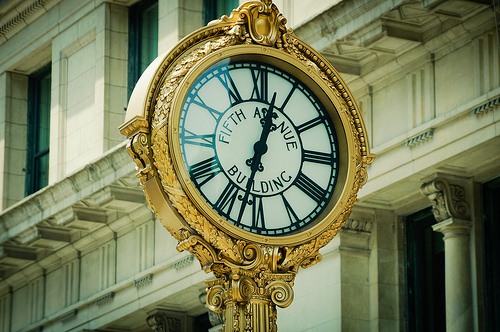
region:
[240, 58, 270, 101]
Small black roman numeral on a clock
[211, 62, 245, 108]
Small black roman numeral on a clock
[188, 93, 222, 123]
Small black roman numeral on a clock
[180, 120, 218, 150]
Small black roman numeral on a clock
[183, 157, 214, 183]
Small black roman numeral on a clock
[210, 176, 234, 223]
Small black roman numeral on a clock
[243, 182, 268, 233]
Small black roman numeral on a clock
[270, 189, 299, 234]
Small black roman numeral on a clock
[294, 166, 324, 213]
Small black roman numeral on a clock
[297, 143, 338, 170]
Small black roman numeral on a clock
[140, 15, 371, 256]
clock on a pole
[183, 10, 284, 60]
golden frame around clock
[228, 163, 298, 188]
black writing on clock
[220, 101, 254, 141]
black writing on clock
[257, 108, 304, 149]
black writing on clock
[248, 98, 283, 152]
black hand of clock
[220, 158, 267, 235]
black hand of clock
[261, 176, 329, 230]
black roman numerals on clock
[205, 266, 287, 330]
golden pole on bottom of clock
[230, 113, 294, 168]
white face of lcock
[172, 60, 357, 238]
It is in the middle of the afternoon.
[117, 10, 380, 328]
The clock is gold.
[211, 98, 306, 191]
The building is at Fifth Ave.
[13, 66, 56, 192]
The window is shut.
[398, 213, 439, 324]
This window is shut.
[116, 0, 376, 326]
The clock is very ornate.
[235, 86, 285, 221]
The clock hand is black.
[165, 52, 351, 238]
The number are in roman numeral.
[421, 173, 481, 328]
The pillars are ornate.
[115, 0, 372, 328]
THERE A BIG GOLD CLOCK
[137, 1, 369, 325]
THERE A BIG GOLD CLOCK SHAPE IN CURCLE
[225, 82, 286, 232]
THERE A BIG GOLD CLOCK BLACK HANDS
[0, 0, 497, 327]
THE CLOCK IN FRONT OF BUILDING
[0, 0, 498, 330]
THE BUILDING IS WHITE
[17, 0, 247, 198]
THE BUILDING THREE WINDOW UP TOP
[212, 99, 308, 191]
THE CLOCK HAVE WRITING ON IT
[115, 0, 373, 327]
THE CLOCK HAVE DESIGN ON IT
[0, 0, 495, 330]
THE CLOCK AND BUILDING LOOK HISTORY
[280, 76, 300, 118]
Small black roman numeral on a clock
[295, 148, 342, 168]
Small black roman numeral on a clock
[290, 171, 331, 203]
Small black roman numeral on a clock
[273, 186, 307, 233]
Small black roman numeral on a clock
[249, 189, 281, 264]
Small black roman numeral on a clock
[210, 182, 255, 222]
Small black roman numeral on a clock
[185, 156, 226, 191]
Small black roman numeral on a clock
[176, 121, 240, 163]
Small black roman numeral on a clock